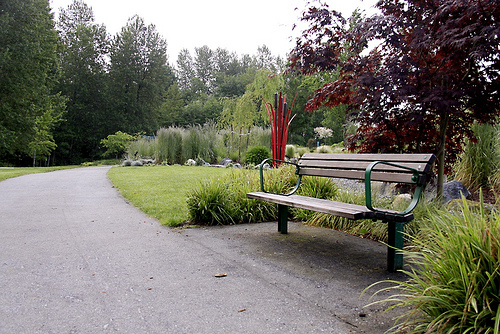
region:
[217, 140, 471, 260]
brown bench on sidewalk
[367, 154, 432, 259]
green armrest on bench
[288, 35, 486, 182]
red buds on tree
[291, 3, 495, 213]
red tree behind bench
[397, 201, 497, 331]
green and grassy bush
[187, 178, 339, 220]
thick grass next to bench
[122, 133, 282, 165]
tall grasses in distance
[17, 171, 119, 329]
sidewalk is light grey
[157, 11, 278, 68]
grey and cloudy sky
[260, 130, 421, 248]
bench is light brown and wooden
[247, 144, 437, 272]
wooden bench on side of path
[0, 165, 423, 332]
concrete path going through park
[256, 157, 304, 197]
green armrest on bench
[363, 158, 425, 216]
green armrest on bench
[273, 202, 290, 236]
green leg of bench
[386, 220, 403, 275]
green leg of bench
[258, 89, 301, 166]
red structure beyond bench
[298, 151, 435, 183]
wooden back of bench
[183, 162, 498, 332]
tall spiky green grass around bench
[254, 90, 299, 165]
red spiked object in grass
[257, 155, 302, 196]
green armrest of bench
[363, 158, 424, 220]
green armrest of bench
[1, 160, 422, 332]
concrete path near bench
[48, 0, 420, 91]
clear white sky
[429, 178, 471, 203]
large dark rock behind bench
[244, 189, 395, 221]
wooden seat of bench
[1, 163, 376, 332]
a paved walkway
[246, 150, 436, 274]
metal and wood parkbench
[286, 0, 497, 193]
medium sized maple tree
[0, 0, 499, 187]
row of green trees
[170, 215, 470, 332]
a concrete foundation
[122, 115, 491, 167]
a variety of plants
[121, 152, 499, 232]
row of decorative stones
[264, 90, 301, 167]
some type of red stalks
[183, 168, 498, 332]
a bunch of shrubbery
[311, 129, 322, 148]
person standing in the distance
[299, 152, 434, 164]
brown wooden slat on bench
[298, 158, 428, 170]
brown wooden slat on bench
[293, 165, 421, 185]
brown wooden slat on bench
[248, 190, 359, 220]
brown wooden slat on bench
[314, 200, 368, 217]
brown wooden slat on bench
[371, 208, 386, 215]
brown wooden slat on bench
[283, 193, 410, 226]
brown wooden slat on bench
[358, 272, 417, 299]
green leaf on bush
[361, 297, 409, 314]
green leaf on bush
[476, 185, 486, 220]
green leaf on bush